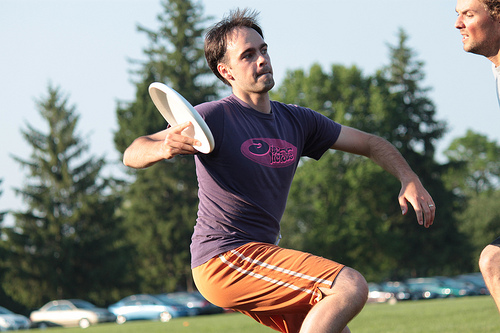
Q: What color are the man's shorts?
A: Orange.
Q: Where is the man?
A: A park.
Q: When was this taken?
A: Daytime.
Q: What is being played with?
A: Frisbee.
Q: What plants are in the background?
A: Trees.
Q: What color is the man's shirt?
A: Purple.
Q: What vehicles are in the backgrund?
A: Cars.